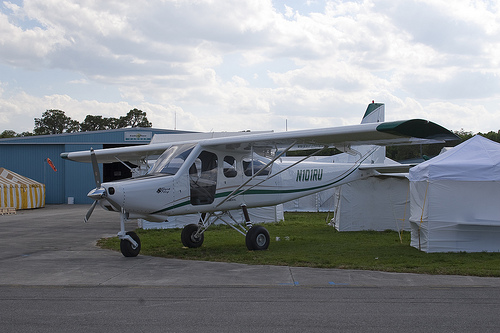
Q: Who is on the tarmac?
A: No one.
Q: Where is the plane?
A: On the grass.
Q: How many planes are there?
A: One.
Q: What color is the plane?
A: White.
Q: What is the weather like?
A: Cloudy.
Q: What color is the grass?
A: Green.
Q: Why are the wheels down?
A: For taxiing.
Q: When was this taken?
A: During the day.